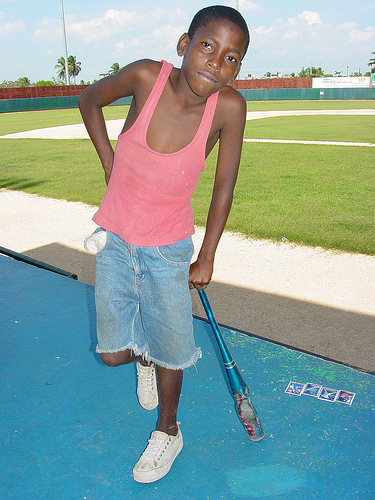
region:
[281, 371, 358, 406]
stamps on the ground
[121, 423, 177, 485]
sneaker on the foot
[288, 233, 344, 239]
grass on the ground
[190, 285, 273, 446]
baseball bat is leaning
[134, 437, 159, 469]
shoelaces on the shoe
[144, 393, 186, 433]
dark skin on boy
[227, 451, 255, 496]
lighter blue spot on ground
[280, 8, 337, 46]
clouds in the sky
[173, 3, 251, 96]
The boys hair is brown.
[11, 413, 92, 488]
The pavement is blue.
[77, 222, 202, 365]
The boy is wearing blue jean shorts.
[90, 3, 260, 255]
The boys is wearing a pink tank top.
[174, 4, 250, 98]
The boys hair is short.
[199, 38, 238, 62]
The boys eyes are brown.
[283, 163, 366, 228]
The grass is green.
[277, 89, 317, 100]
The fence in the background is green.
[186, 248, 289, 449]
Blue and silver baseball bat.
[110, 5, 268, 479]
Boy leaning on baseball bat.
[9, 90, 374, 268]
A freshly cut baseball field.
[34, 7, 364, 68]
Forecast is partly cloudy.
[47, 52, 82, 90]
Green tall palm tre.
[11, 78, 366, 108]
A fence outlining the baseball park.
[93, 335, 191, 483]
Boy with white shoes.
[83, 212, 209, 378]
Boy is wearing dirty blue jean shorts.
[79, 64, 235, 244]
Boy is wearing a pink tank top.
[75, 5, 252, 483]
thin young boy wearing white shoes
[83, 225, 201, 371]
light blue cut off denim jean shorts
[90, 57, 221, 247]
worn pink tank top shirt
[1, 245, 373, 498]
blue roof of the dugout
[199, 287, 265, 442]
worn blue aluminum baseball bat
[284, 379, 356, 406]
four baseball cards lined up in a row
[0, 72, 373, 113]
baseball field wooden fencing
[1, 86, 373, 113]
green fence padding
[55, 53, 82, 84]
two palm trees in the background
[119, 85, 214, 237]
pink top of shirt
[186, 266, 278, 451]
left hand holding bat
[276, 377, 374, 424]
paper on the ground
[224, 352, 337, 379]
green markings on the blue ground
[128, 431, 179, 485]
white shoes on the person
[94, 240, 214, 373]
person wearing jean pants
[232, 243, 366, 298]
white lines by the grass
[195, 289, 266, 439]
bat is blue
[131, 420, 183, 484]
shoe is white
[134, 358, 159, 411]
shoe is white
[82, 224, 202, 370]
shorts are made of jean material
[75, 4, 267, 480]
boys is leaning on the bat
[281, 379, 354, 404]
stickers are on the ground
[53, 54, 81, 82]
palm tree is behind the fence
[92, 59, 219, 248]
shirt is red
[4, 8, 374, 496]
a scene of during the day time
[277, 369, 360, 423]
a couple of baseball cards on the ground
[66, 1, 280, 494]
a black kid with a bat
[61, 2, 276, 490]
a person posing for the camera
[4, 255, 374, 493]
a blue ground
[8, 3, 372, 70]
a sky with clouds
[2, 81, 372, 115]
a blue fence in the background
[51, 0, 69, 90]
a gray pole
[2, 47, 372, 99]
some green trees in the background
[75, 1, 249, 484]
kid wearing pink shirt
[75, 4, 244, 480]
kid holding blue bat on left hand